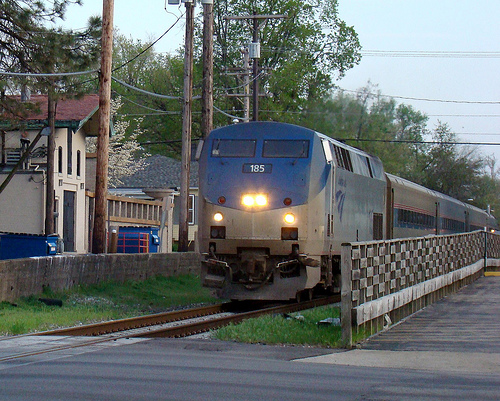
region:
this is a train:
[201, 162, 365, 292]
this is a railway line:
[153, 305, 221, 338]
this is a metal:
[167, 318, 200, 341]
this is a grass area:
[253, 315, 322, 347]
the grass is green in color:
[266, 312, 313, 343]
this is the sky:
[362, 2, 493, 64]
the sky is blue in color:
[399, 8, 459, 33]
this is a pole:
[100, 32, 116, 242]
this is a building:
[28, 102, 83, 232]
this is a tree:
[283, 26, 319, 100]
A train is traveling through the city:
[35, 10, 470, 380]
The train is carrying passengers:
[13, 10, 478, 395]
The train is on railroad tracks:
[6, 20, 487, 378]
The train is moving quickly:
[15, 36, 490, 392]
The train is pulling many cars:
[17, 30, 488, 377]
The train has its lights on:
[30, 35, 497, 381]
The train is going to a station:
[8, 25, 498, 376]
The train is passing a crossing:
[13, 55, 495, 398]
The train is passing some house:
[10, 7, 491, 359]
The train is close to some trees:
[12, 22, 478, 387]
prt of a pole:
[175, 90, 187, 114]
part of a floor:
[430, 315, 460, 362]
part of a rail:
[173, 286, 213, 351]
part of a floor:
[406, 329, 436, 376]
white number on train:
[230, 153, 285, 184]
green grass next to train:
[266, 307, 311, 337]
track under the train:
[155, 295, 230, 335]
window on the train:
[210, 130, 305, 161]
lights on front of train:
[228, 186, 282, 214]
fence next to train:
[325, 232, 487, 314]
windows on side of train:
[388, 203, 448, 235]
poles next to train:
[20, 117, 165, 204]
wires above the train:
[414, 24, 488, 99]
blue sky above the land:
[366, 7, 456, 42]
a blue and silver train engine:
[193, 124, 388, 308]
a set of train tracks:
[1, 293, 342, 364]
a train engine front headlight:
[282, 213, 296, 225]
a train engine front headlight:
[211, 210, 223, 222]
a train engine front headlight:
[242, 192, 255, 209]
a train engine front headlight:
[254, 193, 269, 208]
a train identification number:
[241, 163, 270, 171]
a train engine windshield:
[210, 136, 255, 157]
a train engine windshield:
[261, 140, 307, 157]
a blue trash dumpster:
[0, 230, 60, 260]